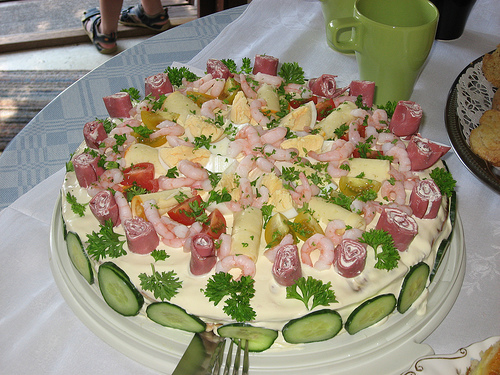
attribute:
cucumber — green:
[95, 255, 146, 319]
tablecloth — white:
[22, 5, 494, 373]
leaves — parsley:
[181, 270, 309, 335]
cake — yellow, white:
[50, 53, 470, 361]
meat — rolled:
[123, 215, 161, 256]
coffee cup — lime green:
[328, 2, 446, 110]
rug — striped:
[15, 64, 95, 144]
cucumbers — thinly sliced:
[291, 287, 398, 345]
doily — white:
[453, 52, 498, 174]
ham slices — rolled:
[61, 39, 470, 321]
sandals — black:
[80, 7, 114, 55]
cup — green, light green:
[325, 0, 440, 109]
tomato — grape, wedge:
[120, 161, 154, 187]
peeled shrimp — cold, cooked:
[213, 252, 257, 284]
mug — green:
[332, 4, 440, 116]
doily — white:
[452, 53, 483, 129]